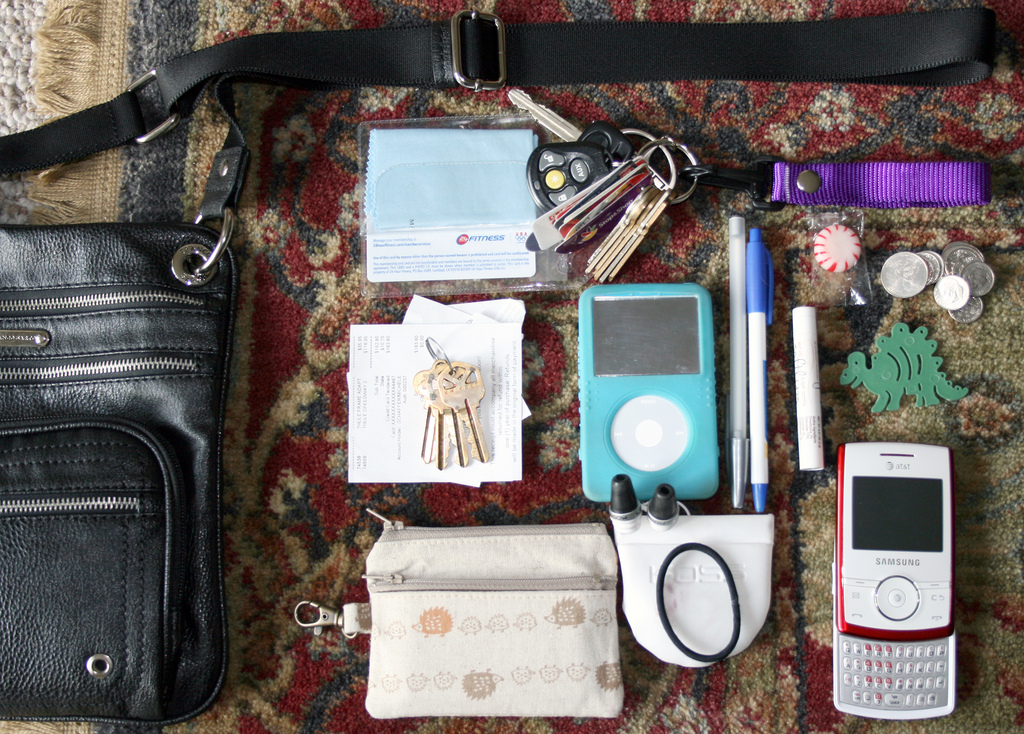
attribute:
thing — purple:
[769, 156, 988, 208]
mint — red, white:
[810, 217, 863, 276]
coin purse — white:
[341, 502, 631, 727]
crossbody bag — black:
[4, 1, 992, 727]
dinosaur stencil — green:
[834, 320, 973, 416]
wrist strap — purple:
[769, 154, 992, 207]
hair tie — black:
[652, 538, 745, 664]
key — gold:
[410, 357, 456, 466]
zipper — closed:
[4, 495, 145, 513]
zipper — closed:
[2, 350, 201, 387]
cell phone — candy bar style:
[828, 435, 958, 725]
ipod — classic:
[573, 282, 721, 503]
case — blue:
[572, 279, 722, 502]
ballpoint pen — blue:
[743, 225, 778, 511]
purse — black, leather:
[4, 217, 244, 730]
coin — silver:
[875, 243, 930, 302]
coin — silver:
[931, 273, 975, 312]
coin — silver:
[946, 290, 985, 325]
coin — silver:
[953, 256, 992, 291]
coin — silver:
[938, 230, 986, 274]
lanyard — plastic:
[346, 112, 569, 309]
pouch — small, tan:
[287, 497, 625, 722]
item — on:
[838, 309, 960, 426]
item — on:
[795, 418, 970, 717]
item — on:
[806, 309, 977, 437]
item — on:
[726, 124, 992, 250]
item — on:
[833, 318, 967, 427]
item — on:
[814, 294, 989, 442]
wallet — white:
[269, 521, 620, 729]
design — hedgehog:
[390, 609, 607, 718]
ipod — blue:
[563, 279, 730, 513]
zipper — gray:
[360, 564, 613, 593]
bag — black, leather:
[11, 217, 230, 717]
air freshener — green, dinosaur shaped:
[839, 334, 956, 404]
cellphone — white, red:
[839, 442, 958, 719]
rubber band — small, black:
[660, 542, 736, 661]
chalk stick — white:
[791, 299, 826, 479]